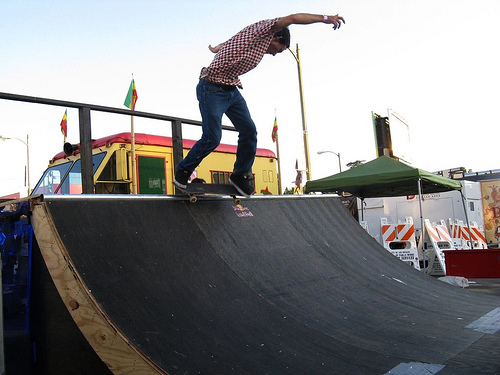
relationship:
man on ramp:
[173, 12, 346, 195] [6, 188, 483, 370]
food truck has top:
[26, 71, 283, 196] [51, 131, 278, 160]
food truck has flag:
[26, 71, 283, 196] [270, 115, 278, 141]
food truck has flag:
[26, 71, 283, 196] [123, 78, 138, 110]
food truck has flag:
[26, 71, 283, 196] [59, 107, 68, 137]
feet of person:
[174, 169, 193, 190] [169, 10, 349, 200]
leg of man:
[225, 105, 257, 174] [173, 12, 346, 195]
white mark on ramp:
[389, 270, 409, 292] [6, 188, 483, 370]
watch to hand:
[318, 9, 337, 31] [329, 7, 354, 35]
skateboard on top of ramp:
[168, 177, 257, 202] [184, 195, 421, 329]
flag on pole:
[271, 116, 278, 143] [272, 115, 285, 196]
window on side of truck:
[135, 155, 167, 195] [26, 115, 287, 200]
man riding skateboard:
[173, 12, 346, 195] [159, 161, 282, 234]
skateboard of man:
[172, 182, 255, 205] [167, 5, 354, 195]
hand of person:
[325, 13, 345, 29] [169, 10, 349, 200]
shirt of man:
[200, 18, 272, 85] [173, 12, 346, 195]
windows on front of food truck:
[33, 160, 99, 192] [30, 132, 279, 196]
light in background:
[312, 144, 339, 161] [49, 58, 496, 168]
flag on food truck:
[272, 117, 278, 143] [30, 132, 279, 196]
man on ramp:
[173, 12, 346, 195] [44, 197, 471, 366]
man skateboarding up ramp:
[167, 5, 354, 195] [6, 188, 483, 370]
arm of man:
[328, 7, 345, 33] [167, 5, 354, 195]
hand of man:
[325, 14, 344, 31] [158, 8, 345, 199]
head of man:
[263, 25, 290, 57] [158, 8, 345, 199]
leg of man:
[226, 105, 258, 200] [167, 5, 354, 195]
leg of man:
[163, 86, 237, 196] [167, 5, 354, 195]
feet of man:
[171, 163, 256, 200] [167, 5, 354, 195]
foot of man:
[224, 173, 260, 200] [167, 5, 354, 195]